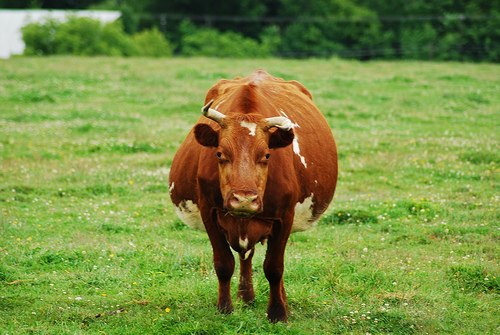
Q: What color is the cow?
A: Brown.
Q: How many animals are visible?
A: One.